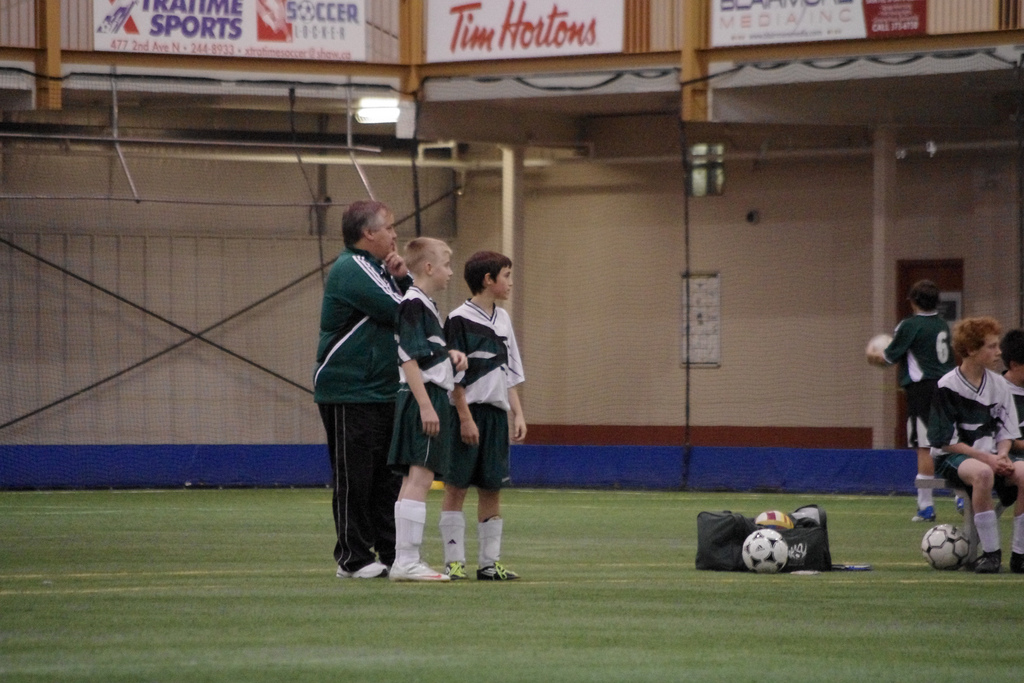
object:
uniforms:
[927, 364, 1024, 510]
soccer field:
[0, 490, 1017, 683]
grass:
[6, 488, 1022, 677]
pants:
[319, 401, 396, 574]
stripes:
[334, 405, 343, 565]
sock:
[438, 509, 465, 565]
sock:
[477, 515, 503, 569]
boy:
[388, 236, 470, 584]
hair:
[401, 236, 454, 280]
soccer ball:
[753, 510, 794, 530]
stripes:
[342, 402, 353, 568]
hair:
[463, 251, 518, 295]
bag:
[697, 504, 834, 573]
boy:
[437, 249, 529, 579]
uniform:
[387, 286, 456, 477]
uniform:
[441, 297, 528, 493]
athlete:
[923, 316, 1024, 570]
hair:
[951, 315, 1002, 361]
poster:
[681, 271, 723, 366]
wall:
[0, 110, 453, 443]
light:
[355, 96, 402, 125]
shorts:
[445, 402, 513, 492]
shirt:
[443, 297, 526, 412]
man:
[309, 199, 416, 579]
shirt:
[391, 285, 456, 391]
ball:
[742, 529, 790, 573]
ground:
[0, 481, 1024, 683]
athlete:
[863, 276, 959, 523]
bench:
[915, 478, 1024, 571]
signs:
[426, 0, 629, 66]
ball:
[920, 523, 973, 570]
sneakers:
[388, 560, 452, 584]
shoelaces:
[476, 561, 522, 582]